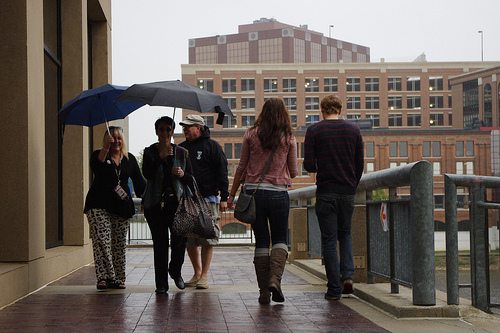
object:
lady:
[230, 97, 297, 307]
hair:
[252, 97, 292, 151]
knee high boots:
[253, 244, 289, 306]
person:
[299, 96, 367, 298]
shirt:
[304, 120, 363, 191]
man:
[180, 117, 226, 290]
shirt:
[141, 140, 188, 209]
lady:
[77, 126, 146, 289]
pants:
[88, 207, 131, 287]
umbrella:
[59, 86, 147, 126]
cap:
[179, 114, 208, 127]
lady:
[137, 117, 194, 295]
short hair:
[153, 116, 176, 136]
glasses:
[158, 125, 175, 135]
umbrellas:
[126, 78, 239, 127]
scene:
[2, 0, 498, 333]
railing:
[358, 165, 499, 303]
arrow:
[379, 206, 387, 227]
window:
[387, 80, 405, 93]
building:
[177, 62, 449, 114]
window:
[389, 140, 398, 158]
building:
[175, 127, 499, 231]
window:
[485, 84, 491, 99]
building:
[448, 67, 500, 128]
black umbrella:
[115, 80, 236, 121]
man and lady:
[145, 113, 222, 299]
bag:
[172, 178, 218, 240]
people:
[57, 80, 364, 303]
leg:
[319, 198, 343, 296]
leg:
[84, 209, 118, 284]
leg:
[147, 207, 169, 293]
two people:
[81, 113, 191, 295]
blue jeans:
[248, 189, 292, 248]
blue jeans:
[317, 194, 354, 299]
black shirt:
[84, 150, 146, 219]